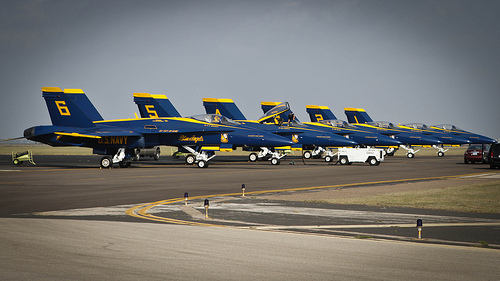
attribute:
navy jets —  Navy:
[23, 85, 499, 164]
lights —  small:
[182, 182, 423, 239]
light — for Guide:
[405, 210, 427, 240]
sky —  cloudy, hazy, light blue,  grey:
[0, 1, 498, 146]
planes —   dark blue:
[85, 117, 286, 205]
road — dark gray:
[5, 153, 496, 278]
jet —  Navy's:
[22, 84, 293, 168]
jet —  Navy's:
[133, 92, 355, 166]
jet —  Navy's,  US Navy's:
[203, 99, 368, 161]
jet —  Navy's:
[260, 101, 401, 164]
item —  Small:
[10, 149, 36, 165]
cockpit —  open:
[254, 102, 306, 127]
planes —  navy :
[25, 88, 280, 252]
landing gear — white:
[101, 143, 138, 168]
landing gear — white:
[178, 138, 215, 167]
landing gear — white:
[245, 143, 287, 168]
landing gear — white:
[308, 145, 331, 162]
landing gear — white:
[386, 144, 418, 158]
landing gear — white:
[462, 144, 480, 156]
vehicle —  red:
[463, 139, 490, 166]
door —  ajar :
[483, 144, 491, 160]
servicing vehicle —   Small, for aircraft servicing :
[337, 142, 387, 167]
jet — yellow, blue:
[41, 85, 230, 159]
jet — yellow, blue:
[132, 88, 262, 143]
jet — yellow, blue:
[264, 93, 356, 140]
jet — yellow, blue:
[201, 95, 321, 135]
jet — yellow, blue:
[402, 116, 470, 141]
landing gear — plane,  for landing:
[246, 142, 288, 166]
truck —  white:
[275, 87, 410, 220]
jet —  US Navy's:
[26, 81, 248, 173]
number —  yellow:
[50, 95, 74, 118]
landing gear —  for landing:
[401, 145, 426, 162]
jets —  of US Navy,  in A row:
[5, 85, 497, 169]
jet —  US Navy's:
[17, 81, 302, 162]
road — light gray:
[227, 230, 378, 279]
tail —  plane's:
[42, 89, 101, 127]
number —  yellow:
[52, 100, 72, 118]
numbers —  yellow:
[50, 100, 70, 118]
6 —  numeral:
[52, 100, 70, 120]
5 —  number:
[144, 102, 159, 122]